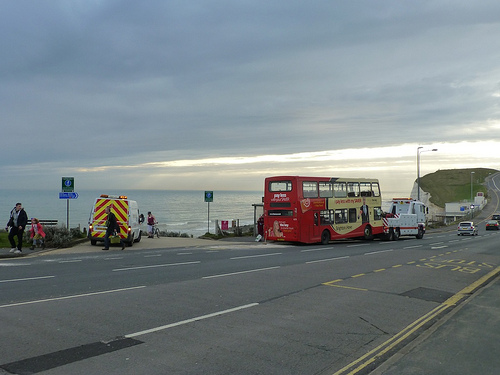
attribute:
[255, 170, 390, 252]
bus — red, double decker, yellow, 2 levels, tall, parked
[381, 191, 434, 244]
tow truck — white, yellow, black, red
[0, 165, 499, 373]
road — paved, long, black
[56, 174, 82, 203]
sign — blue, square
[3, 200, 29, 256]
man — walking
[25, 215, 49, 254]
child — walking, little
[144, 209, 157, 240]
man — standing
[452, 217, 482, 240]
car — white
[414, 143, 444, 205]
street light — overhead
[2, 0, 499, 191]
sky — cloudy, grey, dreary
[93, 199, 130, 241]
doors — striped, yellow, red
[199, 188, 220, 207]
sign — blue, square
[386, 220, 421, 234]
stripe — red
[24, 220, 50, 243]
jacket — pink, girl's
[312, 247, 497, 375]
lines — yellow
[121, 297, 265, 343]
line — white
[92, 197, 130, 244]
stripes — yellow, diagonal, red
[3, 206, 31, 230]
jacket — black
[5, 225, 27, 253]
pants — black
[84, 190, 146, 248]
ambulance — parked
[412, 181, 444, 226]
side — white